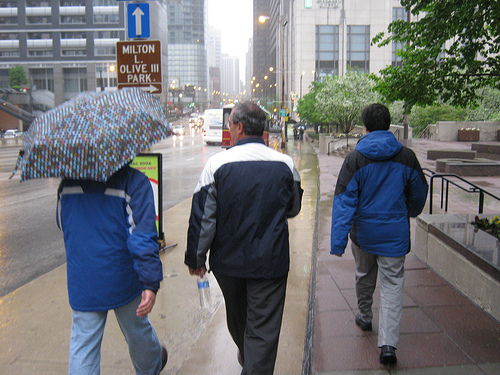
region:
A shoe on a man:
[377, 343, 397, 361]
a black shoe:
[379, 344, 396, 364]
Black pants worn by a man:
[209, 272, 291, 374]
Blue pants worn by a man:
[67, 292, 165, 374]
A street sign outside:
[114, 42, 162, 94]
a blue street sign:
[127, 3, 151, 38]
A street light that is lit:
[258, 14, 284, 114]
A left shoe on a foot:
[353, 314, 373, 331]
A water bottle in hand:
[195, 275, 211, 307]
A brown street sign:
[117, 40, 160, 91]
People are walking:
[58, 104, 425, 371]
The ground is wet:
[1, 136, 498, 374]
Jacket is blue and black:
[330, 129, 427, 259]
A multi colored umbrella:
[12, 90, 172, 184]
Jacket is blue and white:
[185, 140, 300, 275]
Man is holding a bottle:
[187, 261, 212, 306]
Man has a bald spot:
[245, 101, 258, 112]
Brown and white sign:
[115, 41, 160, 93]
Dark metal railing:
[420, 168, 498, 213]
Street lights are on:
[168, 13, 278, 103]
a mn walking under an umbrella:
[7, 87, 174, 186]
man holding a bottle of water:
[188, 262, 213, 309]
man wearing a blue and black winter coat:
[331, 130, 428, 256]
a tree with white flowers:
[316, 73, 383, 130]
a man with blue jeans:
[69, 295, 163, 373]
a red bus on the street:
[221, 105, 269, 152]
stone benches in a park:
[426, 143, 499, 175]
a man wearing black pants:
[214, 270, 285, 374]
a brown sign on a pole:
[115, 41, 165, 93]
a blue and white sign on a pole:
[126, 3, 151, 39]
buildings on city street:
[0, 1, 392, 126]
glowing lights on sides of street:
[173, 67, 283, 104]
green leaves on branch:
[367, 59, 499, 105]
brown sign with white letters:
[116, 38, 161, 93]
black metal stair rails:
[424, 170, 497, 212]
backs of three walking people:
[15, 89, 433, 373]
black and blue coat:
[331, 131, 428, 256]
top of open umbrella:
[13, 88, 169, 183]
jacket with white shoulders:
[184, 138, 300, 278]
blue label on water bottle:
[196, 272, 212, 310]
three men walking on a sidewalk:
[13, 68, 438, 374]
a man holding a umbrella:
[21, 93, 177, 231]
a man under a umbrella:
[26, 86, 168, 223]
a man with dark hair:
[356, 94, 418, 141]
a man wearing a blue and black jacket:
[333, 94, 429, 279]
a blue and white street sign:
[106, 0, 155, 40]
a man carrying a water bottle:
[180, 94, 259, 316]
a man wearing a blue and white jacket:
[172, 101, 310, 306]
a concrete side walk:
[246, 150, 323, 373]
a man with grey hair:
[223, 81, 274, 146]